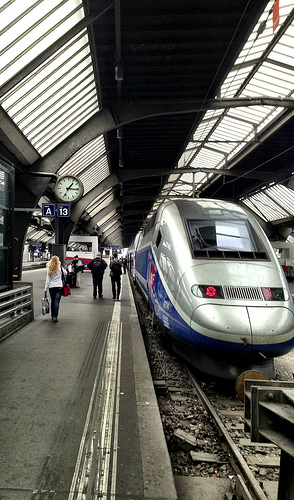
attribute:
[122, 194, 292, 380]
train — blue, silver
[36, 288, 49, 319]
luggage — red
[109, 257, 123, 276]
shirt — grey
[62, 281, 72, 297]
bag — red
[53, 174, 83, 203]
clock — round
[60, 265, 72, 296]
bag — red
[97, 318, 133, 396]
line — white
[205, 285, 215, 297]
light — red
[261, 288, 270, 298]
light — red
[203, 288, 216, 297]
light — red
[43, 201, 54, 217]
background — blue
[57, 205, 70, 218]
background — blue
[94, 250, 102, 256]
hair — gray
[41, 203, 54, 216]
sign — royal blue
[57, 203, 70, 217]
sign — royal blue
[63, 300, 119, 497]
line — white, painted